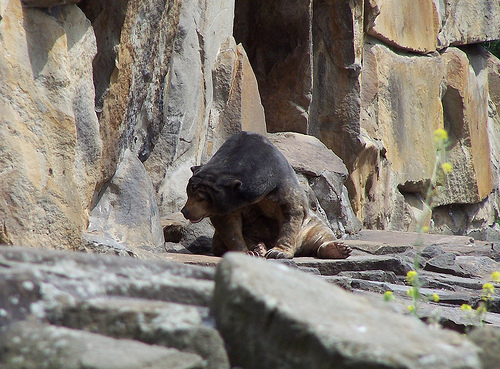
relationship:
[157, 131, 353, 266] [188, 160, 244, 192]
bear has ear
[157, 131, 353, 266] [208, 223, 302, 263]
bear has hand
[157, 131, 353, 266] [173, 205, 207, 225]
bear has mouth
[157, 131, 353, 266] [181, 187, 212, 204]
bear has eye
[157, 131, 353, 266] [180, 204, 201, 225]
bear has nose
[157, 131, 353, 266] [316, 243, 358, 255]
bear has paw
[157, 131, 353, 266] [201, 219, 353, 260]
bear has leg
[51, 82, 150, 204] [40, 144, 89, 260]
wall made of stone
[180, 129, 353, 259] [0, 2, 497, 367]
bear on a rock